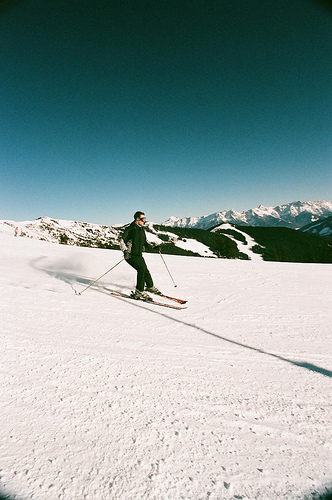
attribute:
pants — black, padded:
[126, 250, 154, 291]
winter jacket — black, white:
[118, 222, 146, 258]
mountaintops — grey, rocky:
[185, 190, 329, 221]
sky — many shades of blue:
[16, 7, 296, 206]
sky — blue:
[0, 0, 328, 222]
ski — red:
[110, 292, 187, 310]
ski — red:
[142, 286, 187, 304]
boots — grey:
[106, 273, 176, 311]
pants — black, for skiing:
[125, 251, 150, 293]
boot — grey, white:
[146, 285, 162, 294]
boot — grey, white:
[129, 289, 152, 300]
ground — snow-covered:
[33, 353, 118, 464]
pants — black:
[122, 252, 155, 292]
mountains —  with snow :
[151, 188, 331, 256]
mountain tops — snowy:
[195, 197, 330, 229]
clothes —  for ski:
[117, 222, 153, 292]